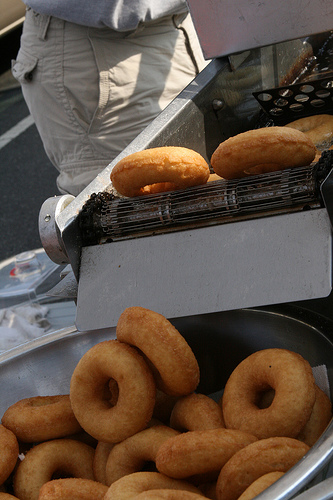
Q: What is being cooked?
A: Donuts.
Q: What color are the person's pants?
A: Tan.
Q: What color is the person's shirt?
A: Grey.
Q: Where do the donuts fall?
A: Into a bowl.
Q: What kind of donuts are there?
A: No frosting.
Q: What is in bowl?
A: Donuts.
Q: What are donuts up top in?
A: Frying machine.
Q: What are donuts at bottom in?
A: Metal bowl.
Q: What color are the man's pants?
A: White.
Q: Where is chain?
A: On roller.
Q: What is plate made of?
A: Metal.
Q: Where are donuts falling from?
A: Conveyer belt.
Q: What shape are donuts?
A: Circular.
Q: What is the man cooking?
A: Doughnuts.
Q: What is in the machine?
A: Doughnuts.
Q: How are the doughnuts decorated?
A: Plainly.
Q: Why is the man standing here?
A: He is making doughnuts.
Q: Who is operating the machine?
A: A man.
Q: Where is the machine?
A: In a factory.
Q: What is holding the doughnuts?
A: A big bowl.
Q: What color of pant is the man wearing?
A: Khaki.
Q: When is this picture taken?
A: The daytime.